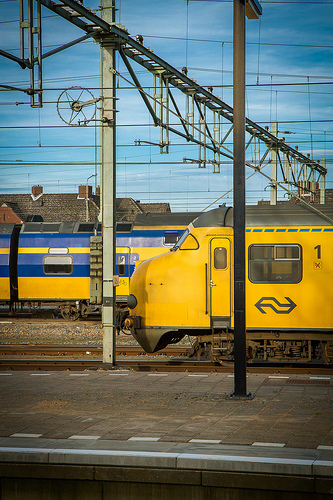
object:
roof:
[4, 193, 26, 202]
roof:
[116, 198, 135, 213]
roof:
[313, 189, 333, 203]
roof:
[7, 202, 23, 224]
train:
[2, 213, 331, 318]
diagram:
[254, 295, 298, 314]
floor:
[171, 428, 204, 436]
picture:
[0, 1, 327, 499]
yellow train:
[124, 201, 331, 361]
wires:
[0, 124, 26, 131]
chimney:
[79, 185, 91, 198]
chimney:
[31, 185, 43, 196]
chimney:
[298, 181, 309, 194]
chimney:
[95, 184, 100, 195]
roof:
[141, 201, 164, 211]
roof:
[132, 199, 145, 216]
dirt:
[34, 396, 56, 409]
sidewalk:
[15, 376, 279, 438]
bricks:
[231, 399, 267, 419]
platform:
[5, 434, 332, 459]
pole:
[231, 4, 246, 391]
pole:
[270, 118, 277, 201]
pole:
[319, 153, 326, 206]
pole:
[98, 2, 117, 369]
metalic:
[132, 47, 146, 55]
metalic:
[246, 124, 258, 133]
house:
[0, 183, 168, 222]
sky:
[4, 0, 327, 194]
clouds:
[288, 48, 299, 63]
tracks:
[87, 354, 98, 368]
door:
[206, 236, 231, 318]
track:
[37, 343, 55, 354]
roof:
[42, 193, 65, 222]